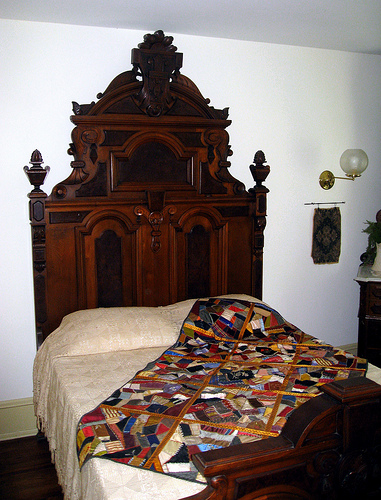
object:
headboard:
[23, 29, 270, 351]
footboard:
[178, 375, 381, 500]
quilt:
[76, 296, 369, 485]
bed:
[23, 29, 381, 500]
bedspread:
[32, 292, 381, 500]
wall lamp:
[319, 147, 370, 189]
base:
[318, 169, 334, 190]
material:
[310, 206, 342, 265]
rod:
[303, 200, 345, 206]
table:
[353, 262, 380, 367]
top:
[352, 264, 380, 283]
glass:
[339, 149, 368, 176]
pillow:
[62, 306, 180, 356]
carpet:
[0, 435, 64, 499]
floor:
[0, 434, 66, 499]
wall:
[1, 19, 380, 441]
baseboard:
[0, 397, 40, 442]